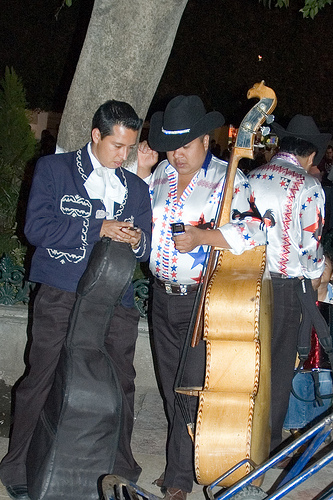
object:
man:
[135, 92, 267, 499]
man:
[248, 114, 324, 471]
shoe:
[160, 486, 189, 500]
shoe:
[157, 471, 167, 488]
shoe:
[270, 452, 295, 469]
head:
[162, 94, 210, 175]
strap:
[297, 279, 315, 362]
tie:
[95, 167, 126, 217]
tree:
[0, 68, 44, 277]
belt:
[156, 278, 200, 296]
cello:
[191, 79, 277, 491]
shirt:
[23, 141, 152, 308]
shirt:
[243, 151, 327, 280]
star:
[306, 196, 312, 204]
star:
[188, 245, 211, 270]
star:
[268, 174, 274, 181]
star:
[165, 199, 171, 206]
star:
[314, 191, 319, 199]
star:
[171, 257, 177, 264]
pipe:
[214, 414, 333, 499]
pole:
[264, 449, 333, 500]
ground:
[0, 306, 333, 500]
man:
[0, 100, 153, 500]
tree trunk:
[53, 0, 190, 171]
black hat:
[147, 94, 224, 152]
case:
[26, 240, 138, 500]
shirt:
[144, 150, 266, 288]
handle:
[218, 77, 279, 229]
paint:
[171, 218, 217, 239]